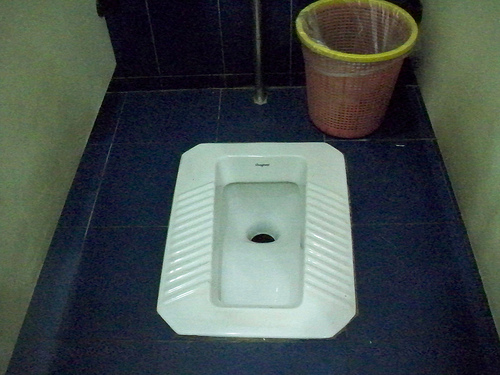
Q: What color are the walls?
A: Green.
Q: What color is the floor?
A: Blue.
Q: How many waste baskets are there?
A: One.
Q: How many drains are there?
A: One.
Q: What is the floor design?
A: Tile.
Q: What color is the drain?
A: White.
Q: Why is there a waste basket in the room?
A: So people can throw their trash away.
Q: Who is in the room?
A: Nobody.